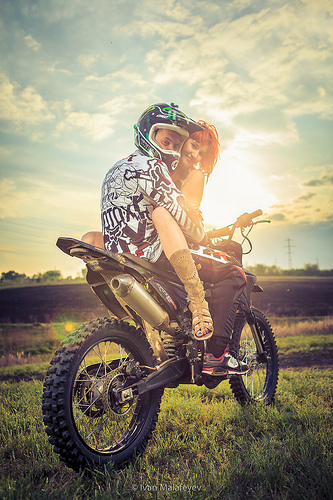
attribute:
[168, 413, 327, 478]
grass — green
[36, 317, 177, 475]
tire — black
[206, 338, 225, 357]
sock — black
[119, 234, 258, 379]
pants — black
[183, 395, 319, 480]
grass — green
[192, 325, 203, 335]
toenail — blue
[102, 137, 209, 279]
shirt — white, black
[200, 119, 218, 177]
hair — red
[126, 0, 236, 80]
clouds — white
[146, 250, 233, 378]
pants — black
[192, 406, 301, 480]
grass — green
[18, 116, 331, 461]
motorcycle — large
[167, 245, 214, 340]
boot — brown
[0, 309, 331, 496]
grass — green